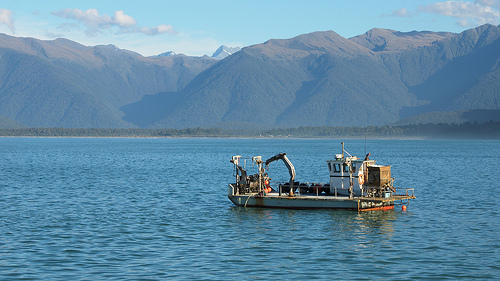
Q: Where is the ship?
A: In the ocean.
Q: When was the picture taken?
A: Daytime.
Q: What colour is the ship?
A: White.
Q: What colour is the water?
A: Blue.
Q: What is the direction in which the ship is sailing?
A: Left.